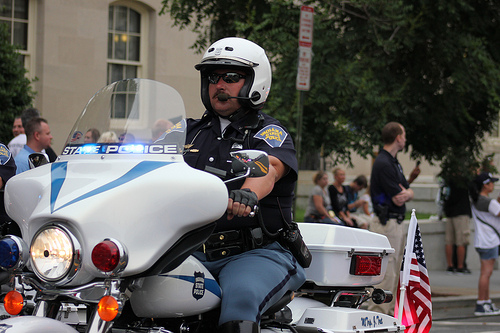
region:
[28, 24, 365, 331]
policeman riding a motorcycle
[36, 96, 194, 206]
"state police" logo on windshield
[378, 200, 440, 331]
American flag on rear of motorcycle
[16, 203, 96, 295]
headlight on front of motorcycle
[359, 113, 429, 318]
man standing on the curb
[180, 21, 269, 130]
policeman wearing white helmet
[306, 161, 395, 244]
people sitting on concrete wall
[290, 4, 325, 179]
red and white traffic sign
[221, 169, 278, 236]
policeman wearing fingerless gloves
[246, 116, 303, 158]
state police patch on uniform sleeve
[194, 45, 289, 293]
This is a policeman on duty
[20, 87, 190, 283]
The front of a white motorcycle..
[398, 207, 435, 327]
A small American flag at the end of the motorcycle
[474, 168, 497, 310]
a female in shorts staring at ....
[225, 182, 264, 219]
A leather glove worn by this policeman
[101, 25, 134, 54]
The lights inside the building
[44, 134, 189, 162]
A sign painted on the front showing :State Police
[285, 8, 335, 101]
A traffic sign with special messages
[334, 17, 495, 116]
A tree by the street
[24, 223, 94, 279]
The main headlight of the motorcycle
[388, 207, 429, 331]
a small American flag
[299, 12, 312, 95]
a pair of no parking signs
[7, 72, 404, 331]
a white police motorcycle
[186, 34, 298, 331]
a motorcycle riding cop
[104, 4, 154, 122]
the window of a building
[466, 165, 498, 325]
a woman with a hat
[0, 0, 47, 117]
another window of a building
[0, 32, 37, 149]
a small green tree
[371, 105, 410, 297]
a man standing by the street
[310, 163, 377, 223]
a group of people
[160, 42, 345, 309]
A police office is riding his motorcycle.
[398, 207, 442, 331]
A flag is on the back of the motorcycle.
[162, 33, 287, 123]
The policeman has on a white helmet.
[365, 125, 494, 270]
People are standing around observing.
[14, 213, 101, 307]
The headlight of the motorcycle is on.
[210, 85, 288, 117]
The police office has a speaker from his helmet next to his mouth.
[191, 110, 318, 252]
The police has on a blue uniform shirt.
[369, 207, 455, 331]
The flag is red, white and blue.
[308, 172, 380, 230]
People are sitting around and watching.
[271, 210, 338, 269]
The police office has a walkie talkie on the side of his pants.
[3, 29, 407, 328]
police officer on a motorcycle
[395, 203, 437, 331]
an american flag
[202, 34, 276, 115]
a white helmet with microphone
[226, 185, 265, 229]
a black fingerless glove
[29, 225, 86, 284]
a front headlight that is on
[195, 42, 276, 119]
a man wearing sunglasses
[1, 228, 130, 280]
red, white and blue lights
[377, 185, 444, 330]
a flag on the back of a motorcycle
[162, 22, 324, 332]
a man in uniform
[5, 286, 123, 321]
two orange round lights